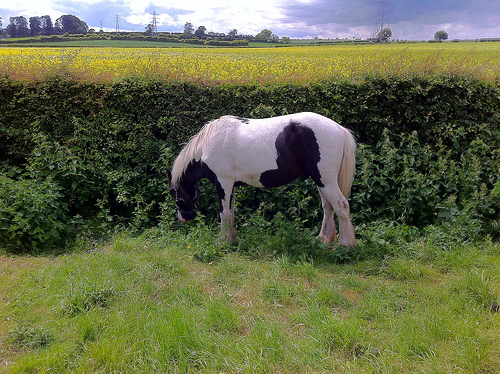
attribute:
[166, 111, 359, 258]
horse — grazing, partial, spotted, white, black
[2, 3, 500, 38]
sky — blue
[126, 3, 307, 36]
cloud — shiny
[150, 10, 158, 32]
power pole — distant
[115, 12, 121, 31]
power pole — distant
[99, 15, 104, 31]
power pole — distant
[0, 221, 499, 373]
grass — luscious, partial, some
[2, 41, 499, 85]
field — distant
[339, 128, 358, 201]
tail — hair, white, long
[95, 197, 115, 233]
plant — green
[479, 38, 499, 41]
train — partisl, partial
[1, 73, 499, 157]
bush — dark, green, thick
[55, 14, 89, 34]
tree — green, grouped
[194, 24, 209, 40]
tree — grouped, green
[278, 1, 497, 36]
cloud — moving in, dark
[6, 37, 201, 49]
ground — partial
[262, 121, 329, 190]
spot — black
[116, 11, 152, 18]
power line — stringed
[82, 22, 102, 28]
power line — stringed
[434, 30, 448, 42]
tree — small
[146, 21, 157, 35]
tree — dead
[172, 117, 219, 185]
mane — white